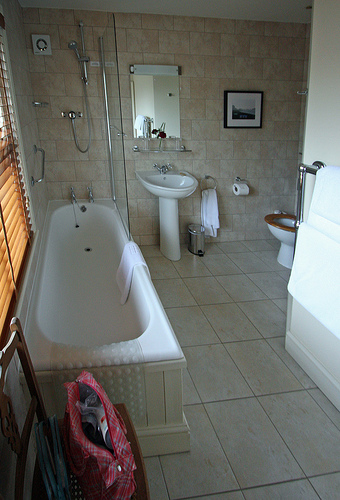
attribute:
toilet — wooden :
[248, 204, 312, 255]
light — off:
[127, 64, 180, 76]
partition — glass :
[95, 17, 136, 237]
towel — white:
[201, 188, 222, 236]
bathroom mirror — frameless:
[131, 61, 183, 142]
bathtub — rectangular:
[30, 178, 187, 379]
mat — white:
[111, 235, 154, 306]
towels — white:
[287, 168, 338, 329]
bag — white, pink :
[62, 370, 139, 495]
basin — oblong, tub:
[13, 197, 192, 458]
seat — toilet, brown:
[263, 211, 297, 232]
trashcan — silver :
[169, 218, 206, 251]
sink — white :
[135, 165, 201, 263]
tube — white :
[97, 408, 122, 450]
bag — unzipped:
[60, 378, 93, 458]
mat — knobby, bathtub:
[46, 336, 149, 428]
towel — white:
[114, 240, 152, 303]